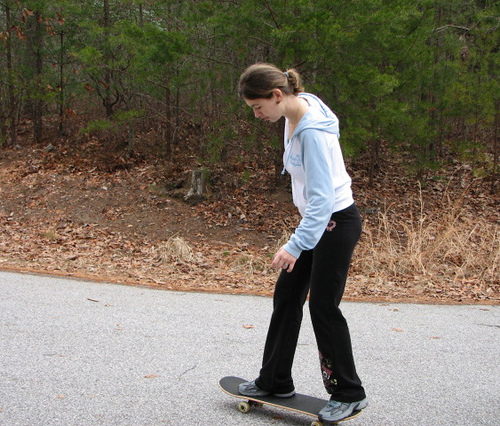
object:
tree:
[184, 0, 499, 179]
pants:
[253, 199, 372, 403]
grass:
[0, 196, 496, 283]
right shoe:
[235, 374, 294, 396]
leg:
[311, 226, 363, 397]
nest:
[458, 46, 469, 60]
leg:
[256, 247, 309, 391]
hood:
[293, 90, 339, 136]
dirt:
[36, 173, 208, 248]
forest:
[2, 0, 499, 184]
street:
[0, 264, 499, 425]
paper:
[218, 377, 366, 421]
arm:
[286, 125, 333, 254]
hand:
[269, 245, 299, 273]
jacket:
[278, 92, 355, 257]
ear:
[270, 88, 284, 103]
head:
[236, 61, 301, 123]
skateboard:
[217, 372, 363, 426]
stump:
[182, 163, 210, 201]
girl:
[235, 56, 365, 426]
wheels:
[234, 399, 253, 413]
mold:
[198, 169, 201, 196]